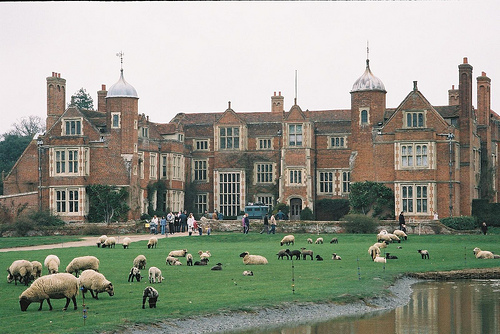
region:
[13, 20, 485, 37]
the grey sky behind the building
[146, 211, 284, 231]
people standing outside a building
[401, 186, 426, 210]
a window of the building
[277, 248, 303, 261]
two black sheeps on the grass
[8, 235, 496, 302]
lots of sheep on grass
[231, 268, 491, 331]
a body of water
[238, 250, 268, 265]
a sheep laying in the grass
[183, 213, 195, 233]
a person wearing a white shirt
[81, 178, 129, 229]
a tree in front of the building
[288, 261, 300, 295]
the pole of a fence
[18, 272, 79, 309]
a sheep on the grass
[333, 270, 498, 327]
water in front of the building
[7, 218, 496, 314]
many sheep in the grass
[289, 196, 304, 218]
the door of the building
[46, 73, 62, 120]
a chimney of the building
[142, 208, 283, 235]
people standing outside of the building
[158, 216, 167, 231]
a person wearing a blue shirt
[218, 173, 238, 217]
a large window on the building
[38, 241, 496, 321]
a wire fence around the water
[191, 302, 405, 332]
rocks around the water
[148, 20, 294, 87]
Sky is white color.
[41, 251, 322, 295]
Grass is green color.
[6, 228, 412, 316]
Sheep are in grass.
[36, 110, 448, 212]
Building is brown color.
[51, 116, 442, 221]
Windows are white color.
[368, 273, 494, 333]
Reflection is seen in water.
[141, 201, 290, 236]
people are standing behind the sheep.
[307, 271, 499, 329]
Water is brown color.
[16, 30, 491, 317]
Day time picture.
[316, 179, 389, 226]
Bushes are green color.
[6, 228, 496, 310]
The sheep on the grass lawn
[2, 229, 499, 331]
The grass lawn the sheep are on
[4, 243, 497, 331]
The fence between the sheep and the water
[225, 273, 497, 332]
The body of water near the sheep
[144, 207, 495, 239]
The people in front of the building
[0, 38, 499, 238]
The large brick building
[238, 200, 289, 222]
The car in front of the building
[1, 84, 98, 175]
The trees behind the building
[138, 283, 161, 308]
The nearest baby sheep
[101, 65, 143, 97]
The dome on the left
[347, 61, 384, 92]
gray dome on top top of house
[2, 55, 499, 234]
large brick manor house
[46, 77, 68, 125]
red brick chimney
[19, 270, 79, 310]
sheep is eating grass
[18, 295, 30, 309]
sheep has a black face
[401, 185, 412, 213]
window next to window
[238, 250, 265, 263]
sheep sitting on top of the grass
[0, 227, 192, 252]
paved walkway behind grass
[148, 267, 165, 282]
white lamb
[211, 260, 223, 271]
black lamb